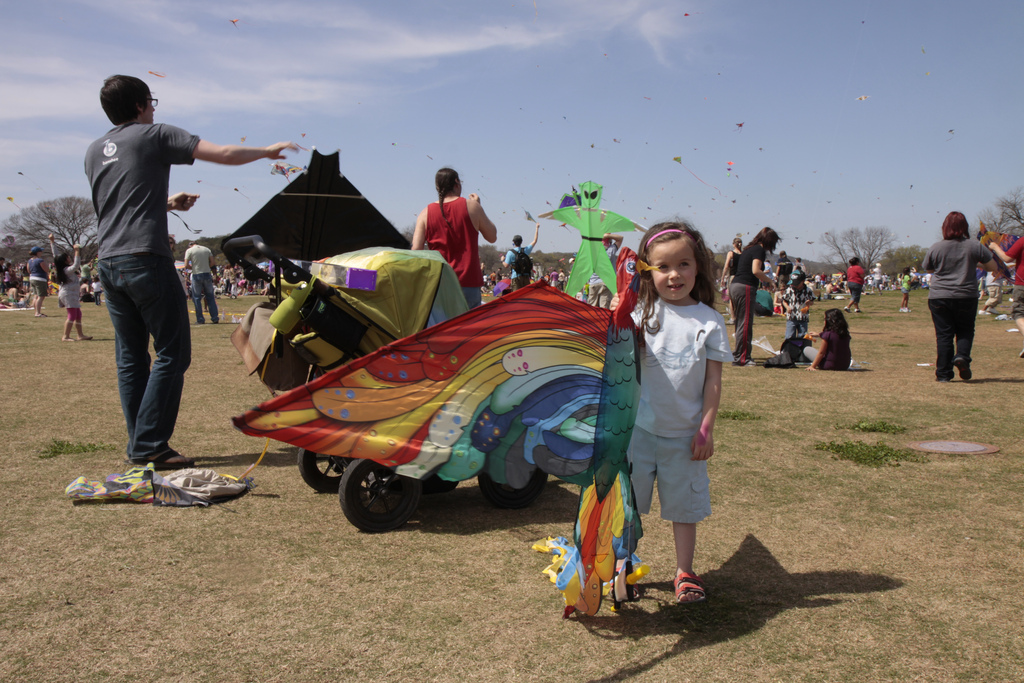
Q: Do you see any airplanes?
A: No, there are no airplanes.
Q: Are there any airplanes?
A: No, there are no airplanes.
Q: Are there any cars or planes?
A: No, there are no planes or cars.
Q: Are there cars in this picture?
A: No, there are no cars.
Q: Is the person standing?
A: Yes, the person is standing.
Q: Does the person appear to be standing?
A: Yes, the person is standing.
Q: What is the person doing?
A: The person is standing.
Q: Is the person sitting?
A: No, the person is standing.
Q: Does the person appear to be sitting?
A: No, the person is standing.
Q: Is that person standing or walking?
A: The person is standing.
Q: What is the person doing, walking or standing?
A: The person is standing.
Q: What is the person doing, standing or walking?
A: The person is standing.